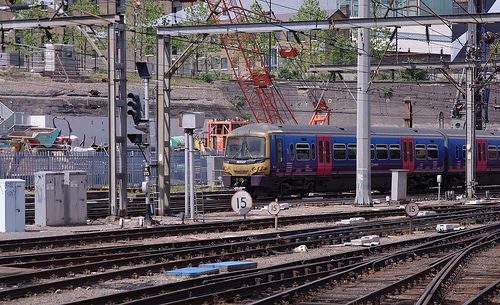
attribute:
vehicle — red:
[202, 3, 332, 155]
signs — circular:
[212, 171, 439, 232]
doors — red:
[308, 131, 338, 177]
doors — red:
[400, 129, 420, 171]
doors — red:
[475, 136, 487, 175]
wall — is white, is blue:
[347, 16, 455, 61]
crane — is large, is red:
[203, 0, 332, 127]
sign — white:
[228, 190, 255, 220]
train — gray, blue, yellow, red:
[221, 125, 496, 196]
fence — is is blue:
[3, 147, 215, 189]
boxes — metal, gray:
[0, 164, 93, 232]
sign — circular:
[222, 181, 277, 226]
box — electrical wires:
[60, 167, 89, 225]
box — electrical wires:
[31, 170, 66, 225]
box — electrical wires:
[0, 178, 26, 233]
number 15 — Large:
[206, 181, 281, 218]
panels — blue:
[172, 255, 261, 283]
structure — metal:
[2, 10, 498, 234]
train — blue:
[219, 110, 498, 200]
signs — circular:
[266, 200, 291, 220]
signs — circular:
[400, 202, 420, 218]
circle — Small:
[267, 204, 285, 220]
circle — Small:
[402, 200, 420, 221]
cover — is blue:
[169, 269, 210, 275]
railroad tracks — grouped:
[0, 193, 498, 300]